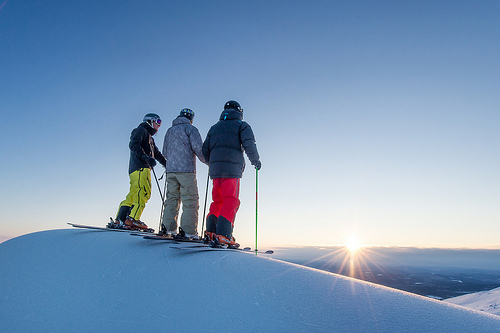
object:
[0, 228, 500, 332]
snow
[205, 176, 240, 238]
pants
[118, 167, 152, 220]
pants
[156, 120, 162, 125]
eyes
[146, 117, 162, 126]
goggles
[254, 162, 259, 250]
pole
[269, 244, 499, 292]
hill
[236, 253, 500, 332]
slope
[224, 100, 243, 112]
hat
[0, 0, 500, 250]
sky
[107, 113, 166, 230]
man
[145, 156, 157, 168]
hand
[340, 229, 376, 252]
sun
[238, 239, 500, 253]
horizon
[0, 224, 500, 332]
hill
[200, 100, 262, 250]
person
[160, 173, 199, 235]
pants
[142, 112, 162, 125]
helmet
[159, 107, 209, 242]
person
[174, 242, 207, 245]
snowboard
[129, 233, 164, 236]
snowboard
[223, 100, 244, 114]
helmet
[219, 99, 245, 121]
head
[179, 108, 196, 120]
helmet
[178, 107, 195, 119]
head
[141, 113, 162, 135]
head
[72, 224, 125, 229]
skis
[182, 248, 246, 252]
skis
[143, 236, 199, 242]
skis